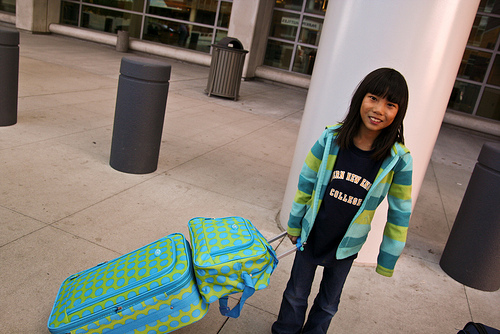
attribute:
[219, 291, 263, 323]
strap — blue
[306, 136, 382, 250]
shirt — black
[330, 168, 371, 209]
letters — white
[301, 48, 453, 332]
girl — young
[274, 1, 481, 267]
pillar — white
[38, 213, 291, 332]
luggage — bright blue, lime green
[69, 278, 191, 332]
zipper — blue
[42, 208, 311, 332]
luggage — teal and lime green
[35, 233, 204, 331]
suitcase — blue, yellow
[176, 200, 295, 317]
suitcase — yellow, blue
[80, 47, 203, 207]
pillar — black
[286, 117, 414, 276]
sweatshirt — blue and green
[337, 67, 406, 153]
hair — black and bangs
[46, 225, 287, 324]
suitcase — blue and green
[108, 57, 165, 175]
cylinders — gray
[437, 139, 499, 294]
cylinders — gray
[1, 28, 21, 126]
cylinders — gray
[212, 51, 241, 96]
lines — vertical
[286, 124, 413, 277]
clothing (implied) — blue, yellow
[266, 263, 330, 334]
pants — black